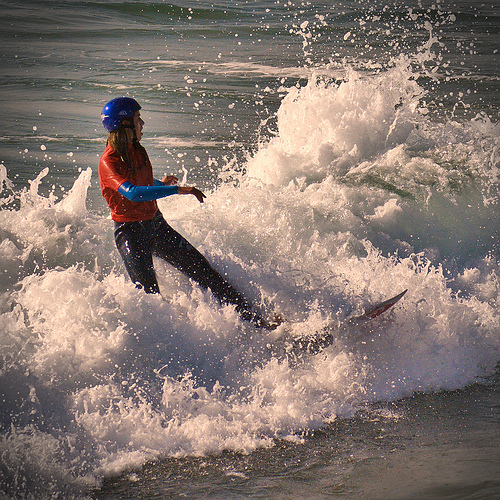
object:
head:
[101, 98, 145, 144]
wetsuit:
[96, 146, 277, 336]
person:
[97, 98, 283, 335]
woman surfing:
[82, 81, 443, 385]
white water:
[0, 64, 500, 444]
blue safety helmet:
[100, 95, 140, 132]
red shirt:
[97, 141, 162, 226]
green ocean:
[2, 3, 498, 500]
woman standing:
[61, 84, 301, 355]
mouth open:
[138, 128, 147, 137]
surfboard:
[239, 286, 408, 356]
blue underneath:
[116, 183, 182, 203]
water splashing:
[28, 56, 496, 403]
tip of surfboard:
[387, 290, 408, 307]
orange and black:
[101, 150, 186, 268]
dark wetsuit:
[111, 208, 274, 337]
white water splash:
[46, 79, 500, 332]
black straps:
[127, 111, 137, 159]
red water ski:
[273, 293, 406, 363]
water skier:
[96, 98, 280, 332]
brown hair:
[104, 125, 132, 176]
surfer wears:
[94, 143, 273, 338]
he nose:
[137, 117, 143, 124]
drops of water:
[0, 0, 500, 500]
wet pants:
[113, 212, 274, 330]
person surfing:
[97, 96, 406, 366]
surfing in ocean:
[36, 71, 500, 495]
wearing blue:
[115, 181, 181, 201]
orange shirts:
[98, 143, 161, 225]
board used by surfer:
[281, 290, 407, 358]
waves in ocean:
[0, 76, 497, 409]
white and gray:
[20, 268, 283, 392]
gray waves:
[0, 76, 500, 499]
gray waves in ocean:
[29, 9, 494, 151]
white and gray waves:
[167, 27, 499, 394]